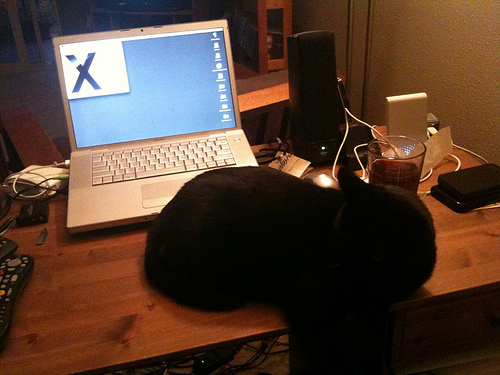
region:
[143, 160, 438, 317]
a black cat laying on top of a desk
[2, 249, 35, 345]
a remote control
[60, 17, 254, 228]
a laptop computer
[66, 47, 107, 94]
a huge x on a computer screen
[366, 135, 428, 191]
a glass containing a liquid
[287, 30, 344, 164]
a computer speaker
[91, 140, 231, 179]
a keyboard on a laptop computer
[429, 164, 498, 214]
a router for a computer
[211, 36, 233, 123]
icons on a computer screen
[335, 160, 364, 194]
a cat's ear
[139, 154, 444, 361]
A black cat.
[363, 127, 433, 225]
A clear glass.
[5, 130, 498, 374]
A wooden table.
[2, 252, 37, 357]
A remote control to a TV.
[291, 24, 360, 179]
A long black computer speaker.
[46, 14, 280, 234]
A laptop computer.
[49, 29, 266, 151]
A bright laptop screen turned on.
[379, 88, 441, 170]
A small white computer speaker.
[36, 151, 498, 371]
A black cat sitting by a computer on a table.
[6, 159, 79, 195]
Computer wires plugged into the computer.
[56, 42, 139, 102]
X on the computer screen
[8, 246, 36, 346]
remote on the desk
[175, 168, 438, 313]
black cat on desk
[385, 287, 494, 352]
drawer on front of desk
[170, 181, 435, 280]
cat is black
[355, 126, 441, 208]
glass on desk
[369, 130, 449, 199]
glass is half full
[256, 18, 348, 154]
speaker next to laptop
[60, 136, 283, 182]
keyboard of the laptop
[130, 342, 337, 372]
cords under the desk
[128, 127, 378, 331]
A cat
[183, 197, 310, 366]
A cat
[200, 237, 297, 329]
A cat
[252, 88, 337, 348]
A cat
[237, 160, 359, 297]
A cat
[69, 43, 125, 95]
an X on the screen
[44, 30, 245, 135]
the laptop screen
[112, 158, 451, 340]
a cat on the desk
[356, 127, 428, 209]
drink behind the cat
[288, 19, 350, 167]
speaker on the desk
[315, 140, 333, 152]
green light on speaker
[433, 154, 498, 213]
phone on the desk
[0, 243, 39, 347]
a remote control on the desk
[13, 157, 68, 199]
wires in the laptop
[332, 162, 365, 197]
the ear of the cat